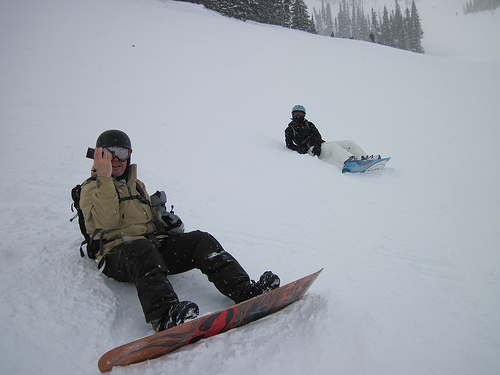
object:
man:
[64, 130, 281, 331]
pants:
[310, 138, 368, 161]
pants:
[98, 228, 252, 324]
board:
[343, 157, 392, 173]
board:
[93, 267, 325, 374]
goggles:
[100, 145, 133, 161]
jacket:
[79, 165, 172, 268]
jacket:
[284, 120, 326, 155]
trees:
[174, 0, 427, 57]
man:
[281, 102, 394, 176]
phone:
[85, 145, 114, 160]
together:
[70, 100, 381, 332]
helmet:
[96, 129, 132, 154]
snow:
[0, 0, 177, 131]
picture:
[1, 1, 500, 374]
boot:
[152, 299, 202, 334]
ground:
[0, 1, 499, 374]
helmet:
[291, 104, 306, 115]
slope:
[0, 1, 499, 374]